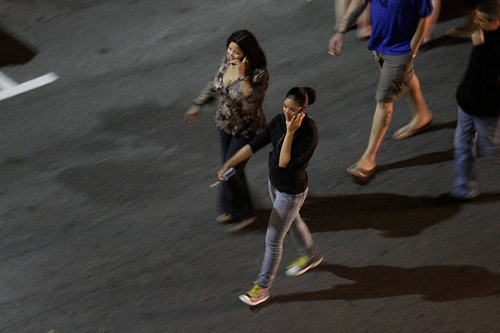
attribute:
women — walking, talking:
[184, 30, 324, 307]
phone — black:
[230, 53, 246, 67]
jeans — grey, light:
[256, 177, 316, 286]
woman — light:
[183, 26, 267, 232]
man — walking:
[327, 1, 433, 180]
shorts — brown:
[370, 49, 414, 100]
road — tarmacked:
[0, 0, 499, 331]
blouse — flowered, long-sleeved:
[193, 56, 267, 135]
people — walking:
[184, 1, 499, 307]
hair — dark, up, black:
[284, 84, 316, 106]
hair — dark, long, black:
[226, 29, 267, 69]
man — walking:
[440, 4, 499, 201]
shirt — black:
[457, 29, 499, 118]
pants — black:
[216, 126, 256, 218]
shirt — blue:
[367, 0, 434, 55]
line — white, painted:
[1, 70, 60, 104]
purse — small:
[210, 166, 236, 189]